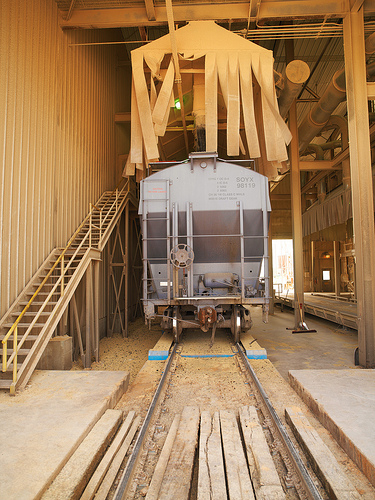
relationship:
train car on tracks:
[132, 157, 277, 332] [126, 327, 293, 499]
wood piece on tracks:
[244, 408, 275, 493] [126, 327, 293, 499]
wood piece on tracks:
[162, 406, 191, 492] [126, 327, 293, 499]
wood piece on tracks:
[219, 411, 245, 496] [126, 327, 293, 499]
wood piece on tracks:
[201, 406, 223, 498] [126, 327, 293, 499]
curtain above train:
[133, 29, 280, 167] [140, 153, 268, 345]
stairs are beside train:
[60, 182, 129, 248] [141, 155, 269, 328]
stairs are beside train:
[4, 244, 98, 394] [141, 155, 269, 328]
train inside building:
[140, 153, 268, 345] [2, 1, 370, 491]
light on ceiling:
[173, 98, 180, 110] [115, 28, 369, 115]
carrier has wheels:
[134, 146, 273, 338] [166, 305, 244, 342]